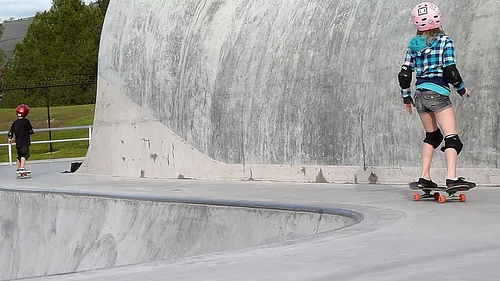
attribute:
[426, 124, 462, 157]
kneepad — blackish, dark, black, protecting, clothing, attached, worn, material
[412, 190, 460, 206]
wheels — red, white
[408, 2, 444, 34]
helmet — pink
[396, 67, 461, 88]
elbow pads — black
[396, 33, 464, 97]
shirt — checkered, turquoise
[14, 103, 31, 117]
helmet — red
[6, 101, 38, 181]
boy — riding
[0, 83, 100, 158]
fence — silver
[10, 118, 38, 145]
shirt — black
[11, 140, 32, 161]
shorts — black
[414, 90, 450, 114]
shorts — denim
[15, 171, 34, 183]
wheels — orange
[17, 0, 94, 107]
tree — green, large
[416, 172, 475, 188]
shoes — black